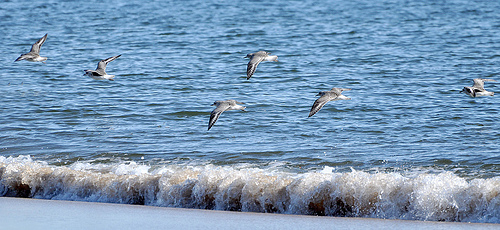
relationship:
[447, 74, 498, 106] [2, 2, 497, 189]
bird close to water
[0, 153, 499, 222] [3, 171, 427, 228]
surf crashing on beach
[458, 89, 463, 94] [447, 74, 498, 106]
beak on bird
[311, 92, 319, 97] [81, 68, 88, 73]
beak on beak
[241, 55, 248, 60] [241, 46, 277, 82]
beak on bird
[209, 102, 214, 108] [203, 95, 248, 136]
beak on bird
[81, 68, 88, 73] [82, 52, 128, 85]
beak on bird